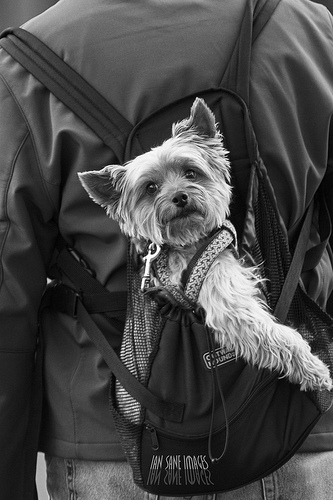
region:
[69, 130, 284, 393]
dog in person's backpack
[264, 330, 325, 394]
paw of the dog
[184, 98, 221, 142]
ear of the dog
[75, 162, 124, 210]
ear of the dog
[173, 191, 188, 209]
nose of the dog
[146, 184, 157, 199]
eye of the dog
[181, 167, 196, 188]
eye of the dog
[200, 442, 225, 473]
cord on the bag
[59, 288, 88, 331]
buckle on the bag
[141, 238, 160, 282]
clasp of the leash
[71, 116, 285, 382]
The dog is in the bag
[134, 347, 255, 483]
The bag is black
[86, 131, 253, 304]
The dog is white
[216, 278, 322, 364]
The dog is furry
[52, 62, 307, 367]
A man is carrying the bag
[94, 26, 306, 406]
The bag is holding the dog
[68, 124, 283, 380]
The dog is being held in a backpack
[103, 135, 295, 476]
The small backpack holds a dog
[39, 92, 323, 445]
The bag has many straps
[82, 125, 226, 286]
The dog is turning its head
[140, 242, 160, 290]
the metal latch on the dog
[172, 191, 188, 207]
the dogs black nose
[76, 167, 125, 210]
the ear on the dog's head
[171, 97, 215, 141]
the ear on the dog's head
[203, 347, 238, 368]
the tag on the bag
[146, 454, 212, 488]
the words on the bag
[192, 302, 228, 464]
the cord hanging on the bag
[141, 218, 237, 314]
the harness on the dog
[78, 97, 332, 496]
the dog in the bag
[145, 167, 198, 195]
the dog's two eyes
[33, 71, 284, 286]
a dog in a backgpack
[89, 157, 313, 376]
the dog looks surprised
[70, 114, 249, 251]
this pup is being carried around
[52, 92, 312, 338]
this is a "doggy pack"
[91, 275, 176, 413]
netting on the doggy pack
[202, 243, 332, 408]
the dog's leg hang outside of the pack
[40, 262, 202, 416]
straps on the bag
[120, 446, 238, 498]
the name of the doggy pack manufacturer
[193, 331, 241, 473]
a hanging string on the backpack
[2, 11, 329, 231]
this person has on a jacket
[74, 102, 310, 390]
puppy looking at camera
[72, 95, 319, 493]
dog in bag on shoulder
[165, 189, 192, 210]
dog with black nose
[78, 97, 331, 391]
furry dog in bag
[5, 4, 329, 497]
dog on person's back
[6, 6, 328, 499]
person carrying dog on his back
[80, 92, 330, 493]
dog in black bag on person's back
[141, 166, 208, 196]
dog has black eyes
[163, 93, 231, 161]
dog has ear perked up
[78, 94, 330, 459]
dog posing for camera